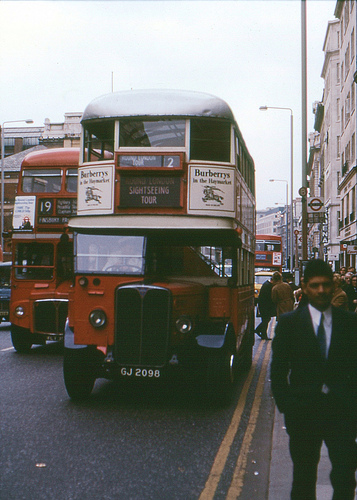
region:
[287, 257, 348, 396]
a man wearing a suit and tie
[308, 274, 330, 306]
a face of a man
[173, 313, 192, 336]
the headlight of a bus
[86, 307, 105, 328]
the headlight of a bus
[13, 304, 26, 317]
the headlight of a bus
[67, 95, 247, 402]
an orange and white double decker bus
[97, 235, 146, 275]
the driver of a bus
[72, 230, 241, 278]
a windshield of a bus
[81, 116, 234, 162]
the windows of a bus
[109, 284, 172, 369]
the grill on a the front of a bus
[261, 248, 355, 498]
Man wearing a black suit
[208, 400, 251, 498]
Yellow lines painted on the road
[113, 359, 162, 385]
Tag on the front of a bus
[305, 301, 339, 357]
White shirt and black tie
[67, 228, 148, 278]
Bus driver inside the bus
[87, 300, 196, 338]
Headlights on a bus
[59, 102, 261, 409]
Red and white double decker bus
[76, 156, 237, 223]
Advertisements on the front of a bus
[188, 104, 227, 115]
Dent on the top of the bus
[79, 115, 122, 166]
Open windshield area on front of a bus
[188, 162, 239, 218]
Burberrys sign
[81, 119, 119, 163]
Window without glass on a bus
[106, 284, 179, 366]
Grill on front of a bus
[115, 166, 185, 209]
Sightseeing sign on a bus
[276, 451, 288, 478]
Grey sidewalk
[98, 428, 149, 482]
Dark grey pavement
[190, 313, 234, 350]
Fender over wheel on a bus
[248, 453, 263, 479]
Litter on the street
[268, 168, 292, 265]
Streetlight on a metal pole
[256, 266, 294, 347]
People walking on the street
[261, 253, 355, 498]
man in a suit and tie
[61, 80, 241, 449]
red and white two decker bus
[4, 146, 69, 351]
red two decker bus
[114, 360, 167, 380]
numeration on bus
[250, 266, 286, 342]
man walking in the street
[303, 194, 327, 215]
traffic sign posted on a pole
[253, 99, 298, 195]
white lamp posts on street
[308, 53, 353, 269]
tall beige building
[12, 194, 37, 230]
advertising on the side of the bus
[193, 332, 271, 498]
set of double yellow lines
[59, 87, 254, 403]
Two level red and white bus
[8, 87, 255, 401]
Two bi-level red buses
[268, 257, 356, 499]
Dark man wearing a dark suit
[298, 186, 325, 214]
Two street signs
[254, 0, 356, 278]
Tall commercial buildings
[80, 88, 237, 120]
Shiny silver bus roof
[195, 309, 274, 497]
Yellow parallel lines on the side of a road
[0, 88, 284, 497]
Three buses driving on a street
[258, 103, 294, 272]
Tall metal street lamps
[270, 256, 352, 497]
Man with his hand in his suit pocket